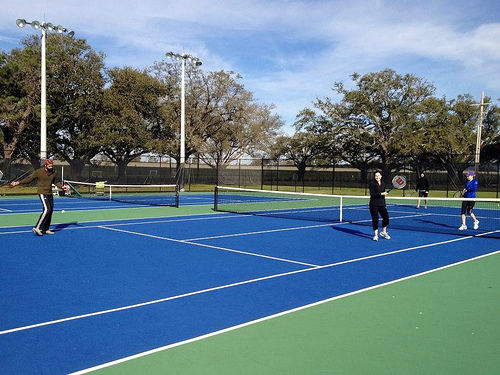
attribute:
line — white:
[160, 258, 310, 298]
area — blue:
[19, 233, 149, 283]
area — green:
[321, 315, 498, 353]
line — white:
[88, 218, 329, 272]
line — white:
[0, 226, 101, 237]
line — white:
[138, 215, 286, 227]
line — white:
[424, 209, 462, 221]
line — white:
[286, 205, 368, 215]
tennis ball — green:
[58, 208, 70, 215]